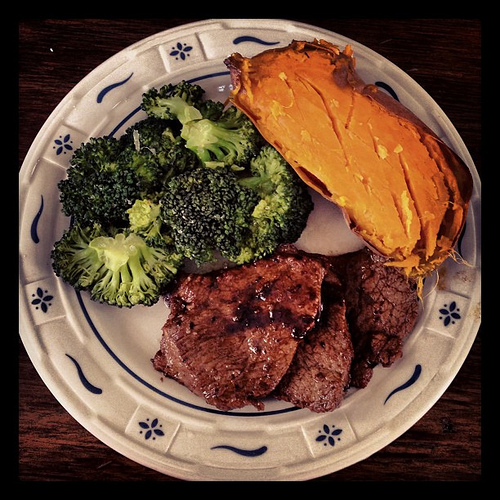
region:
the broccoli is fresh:
[97, 117, 232, 311]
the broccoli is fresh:
[117, 195, 161, 222]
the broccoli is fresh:
[107, 141, 308, 383]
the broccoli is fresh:
[86, 142, 188, 272]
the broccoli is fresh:
[96, 118, 188, 215]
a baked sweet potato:
[226, 35, 477, 257]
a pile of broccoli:
[66, 97, 258, 269]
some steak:
[141, 258, 423, 415]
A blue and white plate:
[29, 32, 492, 459]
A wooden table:
[11, 3, 486, 498]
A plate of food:
[47, 13, 479, 441]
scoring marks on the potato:
[293, 77, 440, 223]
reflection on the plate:
[211, 74, 237, 96]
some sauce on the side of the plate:
[427, 255, 492, 323]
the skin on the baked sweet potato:
[209, 28, 477, 286]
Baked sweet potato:
[220, 37, 475, 277]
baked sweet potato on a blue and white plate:
[221, 43, 478, 279]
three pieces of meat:
[154, 231, 430, 413]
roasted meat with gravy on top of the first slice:
[166, 248, 421, 415]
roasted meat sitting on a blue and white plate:
[149, 253, 421, 411]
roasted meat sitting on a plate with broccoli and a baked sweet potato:
[154, 248, 426, 424]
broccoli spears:
[57, 88, 306, 291]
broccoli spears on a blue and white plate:
[55, 85, 310, 300]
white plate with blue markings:
[16, 27, 497, 461]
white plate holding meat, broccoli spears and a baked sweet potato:
[17, 25, 459, 470]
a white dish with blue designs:
[11, 10, 490, 492]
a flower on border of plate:
[129, 407, 172, 449]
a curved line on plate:
[203, 435, 275, 462]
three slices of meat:
[140, 242, 432, 418]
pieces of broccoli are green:
[51, 76, 298, 307]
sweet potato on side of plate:
[237, 43, 471, 263]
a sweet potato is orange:
[235, 46, 469, 268]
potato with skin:
[217, 37, 474, 281]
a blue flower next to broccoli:
[46, 127, 78, 164]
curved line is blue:
[23, 185, 50, 250]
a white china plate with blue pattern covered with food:
[9, 5, 490, 492]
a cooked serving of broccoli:
[73, 85, 288, 278]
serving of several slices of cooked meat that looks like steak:
[160, 270, 400, 400]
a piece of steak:
[176, 275, 301, 401]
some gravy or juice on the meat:
[236, 288, 306, 338]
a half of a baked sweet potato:
[231, 44, 466, 276]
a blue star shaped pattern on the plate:
[163, 41, 203, 69]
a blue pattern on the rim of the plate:
[54, 343, 116, 423]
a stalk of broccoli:
[129, 251, 145, 302]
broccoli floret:
[171, 183, 244, 243]